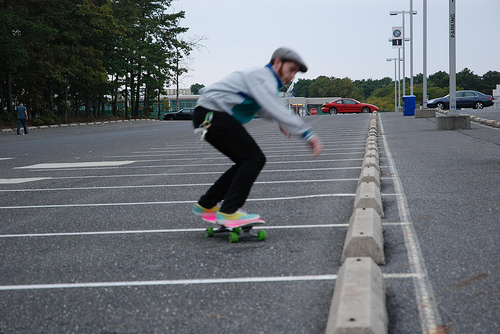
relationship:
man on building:
[12, 100, 31, 135] [96, 85, 346, 119]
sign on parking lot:
[307, 104, 320, 117] [2, 105, 497, 331]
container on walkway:
[403, 92, 417, 114] [380, 107, 498, 332]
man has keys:
[188, 46, 333, 240] [192, 117, 215, 144]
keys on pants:
[192, 117, 215, 144] [184, 102, 279, 210]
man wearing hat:
[192, 46, 323, 230] [266, 42, 317, 77]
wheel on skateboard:
[255, 227, 268, 241] [188, 202, 275, 246]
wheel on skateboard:
[225, 229, 239, 243] [188, 202, 275, 246]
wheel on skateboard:
[203, 224, 213, 238] [188, 202, 275, 246]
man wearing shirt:
[17, 102, 29, 136] [16, 106, 26, 116]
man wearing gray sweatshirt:
[192, 46, 323, 230] [194, 67, 317, 138]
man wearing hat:
[192, 46, 323, 230] [269, 25, 310, 71]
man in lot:
[192, 46, 323, 230] [3, 103, 499, 330]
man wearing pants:
[188, 46, 333, 240] [186, 102, 272, 218]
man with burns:
[192, 46, 323, 230] [277, 60, 286, 78]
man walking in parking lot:
[17, 102, 29, 136] [2, 105, 497, 331]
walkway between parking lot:
[379, 104, 478, 332] [2, 105, 497, 331]